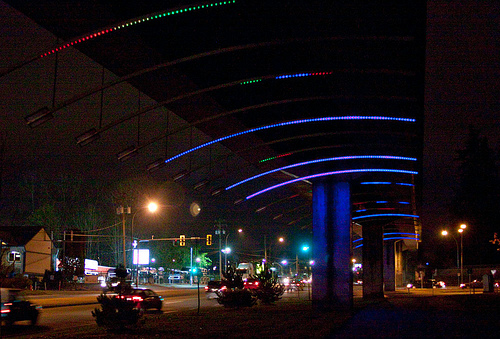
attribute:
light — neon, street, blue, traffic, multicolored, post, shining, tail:
[164, 108, 424, 187]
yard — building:
[369, 251, 491, 302]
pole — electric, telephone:
[252, 149, 429, 216]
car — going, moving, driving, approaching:
[167, 249, 307, 310]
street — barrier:
[161, 218, 415, 306]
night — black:
[88, 131, 127, 169]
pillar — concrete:
[305, 156, 368, 304]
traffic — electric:
[191, 231, 240, 288]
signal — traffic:
[290, 232, 323, 259]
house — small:
[8, 217, 65, 292]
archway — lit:
[282, 86, 431, 218]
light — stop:
[187, 250, 215, 286]